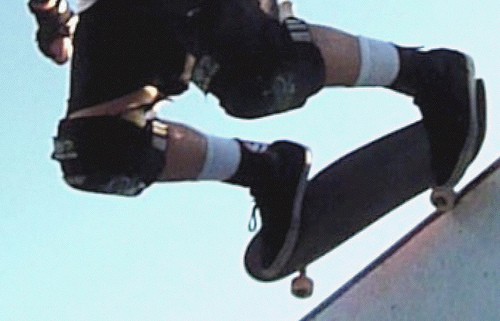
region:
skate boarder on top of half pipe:
[0, 3, 498, 318]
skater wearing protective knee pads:
[0, 0, 499, 305]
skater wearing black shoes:
[34, 25, 494, 285]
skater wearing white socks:
[40, 5, 492, 225]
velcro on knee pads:
[232, 0, 344, 133]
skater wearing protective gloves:
[1, 0, 87, 80]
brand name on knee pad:
[30, 128, 160, 214]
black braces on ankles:
[195, 0, 480, 288]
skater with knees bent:
[22, 5, 492, 285]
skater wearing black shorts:
[0, 0, 497, 312]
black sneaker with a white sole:
[415, 38, 480, 199]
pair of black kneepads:
[51, 7, 291, 197]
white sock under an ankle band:
[350, 30, 425, 95]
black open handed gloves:
[30, 0, 80, 70]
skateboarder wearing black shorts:
[37, 0, 477, 281]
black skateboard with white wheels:
[246, 75, 481, 300]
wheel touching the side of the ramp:
[422, 178, 478, 229]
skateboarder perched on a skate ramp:
[49, 3, 487, 311]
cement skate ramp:
[359, 154, 494, 319]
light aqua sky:
[14, 31, 330, 301]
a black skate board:
[231, 69, 486, 296]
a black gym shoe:
[246, 137, 326, 287]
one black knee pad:
[46, 97, 184, 212]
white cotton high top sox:
[174, 115, 259, 223]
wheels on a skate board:
[259, 180, 459, 301]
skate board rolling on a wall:
[254, 112, 499, 316]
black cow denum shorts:
[31, 0, 285, 150]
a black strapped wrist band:
[22, 0, 80, 61]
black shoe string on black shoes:
[236, 175, 306, 280]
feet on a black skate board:
[246, 50, 487, 285]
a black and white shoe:
[424, 49, 476, 193]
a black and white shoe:
[251, 138, 313, 274]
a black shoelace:
[247, 203, 256, 235]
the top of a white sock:
[200, 133, 244, 183]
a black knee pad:
[50, 116, 171, 197]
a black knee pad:
[190, 20, 323, 116]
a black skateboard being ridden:
[242, 73, 487, 278]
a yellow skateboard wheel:
[290, 272, 310, 295]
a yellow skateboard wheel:
[427, 187, 459, 208]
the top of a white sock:
[356, 37, 401, 92]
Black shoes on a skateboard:
[213, 139, 312, 251]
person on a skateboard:
[160, 109, 470, 287]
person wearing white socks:
[197, 125, 272, 192]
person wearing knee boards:
[49, 121, 164, 199]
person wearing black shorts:
[75, 24, 182, 119]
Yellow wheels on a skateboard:
[274, 265, 339, 317]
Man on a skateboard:
[208, 145, 485, 240]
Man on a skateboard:
[318, 128, 459, 262]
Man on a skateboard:
[196, 122, 365, 286]